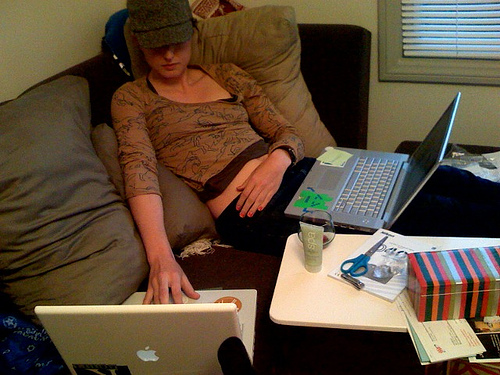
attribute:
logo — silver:
[121, 339, 175, 370]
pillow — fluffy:
[3, 69, 157, 327]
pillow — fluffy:
[188, 4, 345, 173]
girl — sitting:
[81, 3, 313, 289]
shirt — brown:
[111, 79, 297, 186]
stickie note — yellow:
[316, 147, 352, 170]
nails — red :
[231, 204, 271, 220]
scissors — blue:
[338, 232, 390, 277]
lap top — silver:
[258, 96, 440, 245]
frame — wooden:
[373, 1, 497, 82]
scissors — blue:
[342, 235, 397, 275]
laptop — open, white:
[100, 260, 243, 341]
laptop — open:
[286, 89, 464, 229]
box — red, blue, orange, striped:
[406, 239, 499, 327]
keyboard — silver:
[330, 154, 399, 216]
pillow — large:
[161, 7, 335, 160]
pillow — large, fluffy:
[4, 4, 336, 316]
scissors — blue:
[341, 251, 378, 278]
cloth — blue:
[2, 295, 57, 373]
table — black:
[128, 128, 498, 375]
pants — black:
[216, 153, 496, 245]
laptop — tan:
[33, 289, 258, 372]